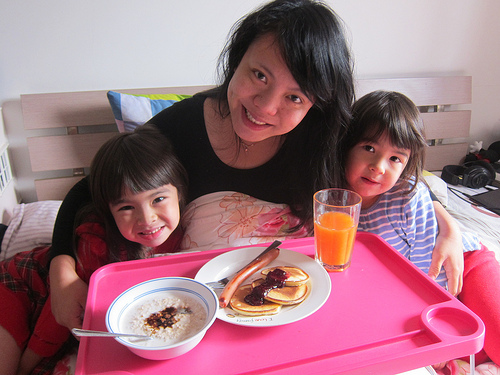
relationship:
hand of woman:
[429, 197, 466, 292] [51, 0, 468, 336]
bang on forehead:
[277, 30, 340, 107] [362, 120, 412, 152]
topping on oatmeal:
[145, 305, 174, 330] [115, 294, 206, 349]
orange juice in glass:
[314, 207, 359, 269] [312, 187, 364, 272]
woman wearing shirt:
[159, 16, 337, 233] [170, 132, 199, 162]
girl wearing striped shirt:
[338, 85, 498, 372] [355, 170, 480, 290]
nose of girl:
[367, 157, 386, 176] [2, 126, 185, 371]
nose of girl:
[138, 205, 156, 225] [338, 87, 458, 297]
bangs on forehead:
[360, 110, 425, 147] [362, 120, 412, 152]